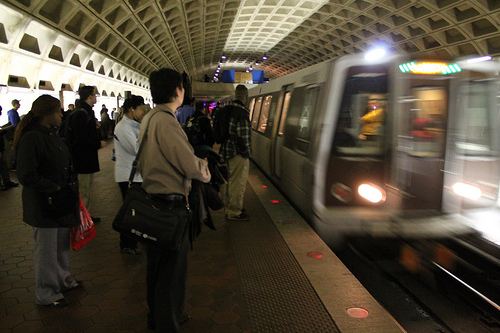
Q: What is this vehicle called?
A: Subway train.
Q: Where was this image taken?
A: Subway platform.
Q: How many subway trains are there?
A: One.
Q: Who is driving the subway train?
A: Conductor.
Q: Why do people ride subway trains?
A: Transportation.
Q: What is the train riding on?
A: Tracks.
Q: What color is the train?
A: White.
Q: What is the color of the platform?
A: Gray.